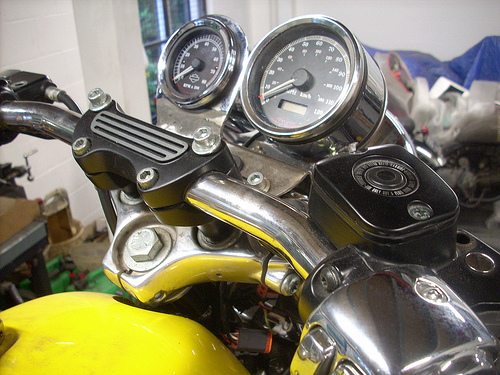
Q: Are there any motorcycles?
A: Yes, there is a motorcycle.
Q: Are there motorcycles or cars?
A: Yes, there is a motorcycle.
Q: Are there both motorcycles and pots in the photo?
A: No, there is a motorcycle but no pots.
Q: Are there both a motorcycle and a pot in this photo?
A: No, there is a motorcycle but no pots.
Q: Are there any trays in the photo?
A: No, there are no trays.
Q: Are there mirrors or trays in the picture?
A: No, there are no trays or mirrors.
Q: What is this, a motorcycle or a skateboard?
A: This is a motorcycle.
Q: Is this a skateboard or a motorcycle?
A: This is a motorcycle.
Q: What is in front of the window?
A: The motorbike is in front of the window.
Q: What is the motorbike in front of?
A: The motorbike is in front of the window.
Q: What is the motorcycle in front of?
A: The motorbike is in front of the window.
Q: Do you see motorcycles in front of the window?
A: Yes, there is a motorcycle in front of the window.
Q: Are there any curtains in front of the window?
A: No, there is a motorcycle in front of the window.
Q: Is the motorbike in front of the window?
A: Yes, the motorbike is in front of the window.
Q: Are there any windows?
A: Yes, there is a window.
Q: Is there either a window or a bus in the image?
A: Yes, there is a window.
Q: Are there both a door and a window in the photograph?
A: No, there is a window but no doors.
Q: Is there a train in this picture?
A: No, there are no trains.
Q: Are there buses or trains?
A: No, there are no trains or buses.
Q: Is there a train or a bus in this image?
A: No, there are no trains or buses.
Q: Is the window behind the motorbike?
A: Yes, the window is behind the motorbike.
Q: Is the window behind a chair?
A: No, the window is behind the motorbike.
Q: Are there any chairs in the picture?
A: No, there are no chairs.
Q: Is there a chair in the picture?
A: No, there are no chairs.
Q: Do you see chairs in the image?
A: No, there are no chairs.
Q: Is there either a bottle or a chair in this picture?
A: No, there are no chairs or bottles.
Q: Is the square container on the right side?
A: Yes, the box is on the right of the image.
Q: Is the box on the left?
A: No, the box is on the right of the image.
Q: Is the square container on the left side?
A: No, the box is on the right of the image.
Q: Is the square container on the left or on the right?
A: The box is on the right of the image.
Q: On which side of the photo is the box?
A: The box is on the right of the image.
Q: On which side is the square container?
A: The box is on the right of the image.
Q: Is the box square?
A: Yes, the box is square.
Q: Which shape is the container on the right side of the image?
A: The box is square.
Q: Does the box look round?
A: No, the box is square.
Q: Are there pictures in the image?
A: No, there are no pictures.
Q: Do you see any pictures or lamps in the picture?
A: No, there are no pictures or lamps.